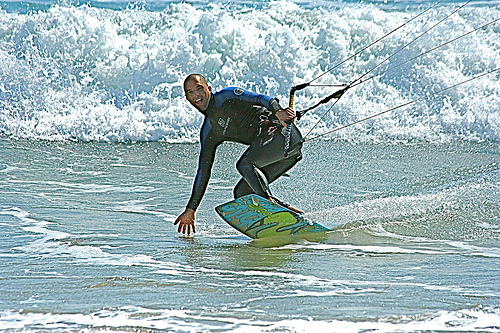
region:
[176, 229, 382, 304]
shadow in the water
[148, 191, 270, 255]
man's hand in the water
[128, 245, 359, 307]
small trail of white waves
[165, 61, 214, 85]
shine on man's forehead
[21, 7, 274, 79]
large wave crashing to shore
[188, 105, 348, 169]
blue and black wet suit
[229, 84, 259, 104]
logo on wet suit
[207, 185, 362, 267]
blue and green surf board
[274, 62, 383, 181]
man's hand holding black cords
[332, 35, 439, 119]
thin black lines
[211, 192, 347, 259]
Yellow, green and blue surf board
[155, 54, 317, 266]
Surfer riding on surfer board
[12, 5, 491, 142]
White crashing waves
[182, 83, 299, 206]
Black and blue body suit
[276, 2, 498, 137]
Wired reins for gliding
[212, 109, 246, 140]
White logo on black body suit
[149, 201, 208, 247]
Hand touching ocean water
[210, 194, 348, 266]
Surfer board riding the waves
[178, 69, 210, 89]
Man's has bald head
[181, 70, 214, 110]
the head of the man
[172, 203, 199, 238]
the hand of the man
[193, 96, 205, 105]
the mouth of the man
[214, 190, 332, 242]
a blue and green surfboard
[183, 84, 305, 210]
a blue and black wet suit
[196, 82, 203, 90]
the eye of the man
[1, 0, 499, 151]
a foaming white wave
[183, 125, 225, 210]
the arm of the man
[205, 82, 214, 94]
the ear of the man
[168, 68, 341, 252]
a man on a surfboard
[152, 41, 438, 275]
a man wind surfing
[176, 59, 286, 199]
a man in a wet suit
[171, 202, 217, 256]
a man's right hand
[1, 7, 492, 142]
a large wave crashing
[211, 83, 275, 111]
blue fabric from a wet suit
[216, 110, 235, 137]
a company logo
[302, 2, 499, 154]
string from the wind surfing contraption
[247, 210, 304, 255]
a green S on the bottom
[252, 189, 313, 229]
a man's feet on a board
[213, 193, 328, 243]
green and blue surfboard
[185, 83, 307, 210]
man wearing blue and black wetsuit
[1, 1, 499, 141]
large white wave behind surfer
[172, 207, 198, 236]
right hand touching water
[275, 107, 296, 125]
left hand holding parasail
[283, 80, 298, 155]
handle to parasail in left hand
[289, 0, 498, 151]
parasail cords in air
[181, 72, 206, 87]
bald head of man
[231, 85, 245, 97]
white patch on right arm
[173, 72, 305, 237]
man smiling while parasailing